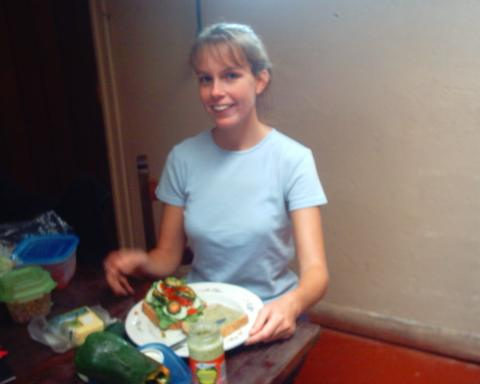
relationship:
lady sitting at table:
[103, 23, 329, 346] [1, 268, 478, 381]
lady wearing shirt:
[103, 23, 329, 346] [157, 129, 329, 340]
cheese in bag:
[72, 312, 100, 330] [36, 319, 83, 354]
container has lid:
[9, 231, 82, 290] [10, 229, 79, 265]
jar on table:
[187, 322, 227, 384] [1, 268, 478, 381]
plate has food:
[117, 267, 299, 377] [140, 278, 246, 344]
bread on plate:
[146, 279, 207, 335] [125, 284, 257, 357]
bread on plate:
[182, 301, 248, 339] [122, 275, 275, 363]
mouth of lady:
[205, 97, 237, 115] [103, 23, 329, 346]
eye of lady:
[223, 71, 249, 79] [103, 23, 329, 346]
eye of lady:
[199, 70, 213, 82] [103, 23, 329, 346]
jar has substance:
[187, 316, 226, 381] [190, 340, 229, 377]